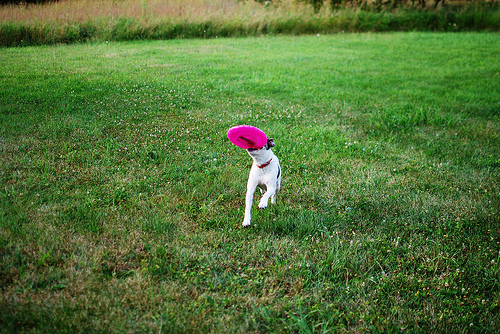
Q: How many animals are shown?
A: One.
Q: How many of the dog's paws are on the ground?
A: Three.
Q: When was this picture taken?
A: Day time.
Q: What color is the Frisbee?
A: Pink.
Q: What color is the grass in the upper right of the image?
A: Yellow.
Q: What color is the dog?
A: White.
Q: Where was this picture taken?
A: A field.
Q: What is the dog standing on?
A: Grass.